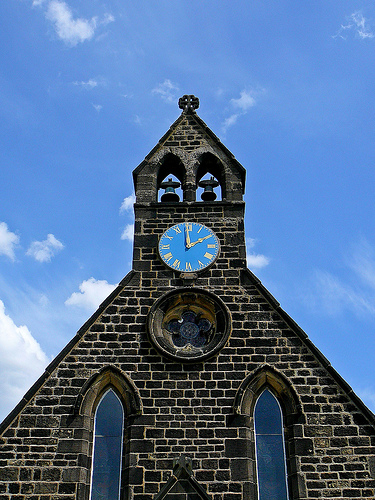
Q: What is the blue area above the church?
A: The sky.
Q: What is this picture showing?
A: A building.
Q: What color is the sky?
A: Blue.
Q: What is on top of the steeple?
A: Clock.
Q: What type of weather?
A: Sunny.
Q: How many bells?
A: Two.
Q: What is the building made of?
A: Brick.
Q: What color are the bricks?
A: Brown.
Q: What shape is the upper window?
A: Circle.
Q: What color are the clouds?
A: White.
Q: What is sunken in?
A: Window pane.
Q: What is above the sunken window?
A: Clock.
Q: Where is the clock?
A: On the front of the church.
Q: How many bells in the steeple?
A: 2.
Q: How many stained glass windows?
A: 2.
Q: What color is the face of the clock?
A: Blue.